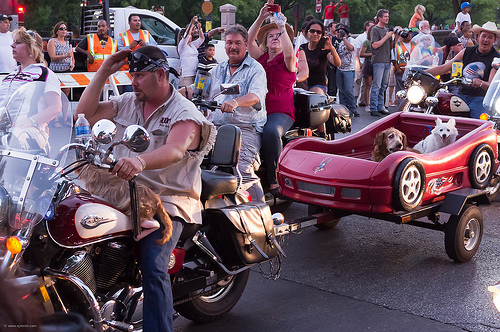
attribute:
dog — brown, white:
[373, 120, 423, 156]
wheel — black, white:
[395, 155, 428, 215]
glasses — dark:
[123, 48, 161, 71]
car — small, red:
[287, 105, 498, 179]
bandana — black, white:
[123, 64, 169, 77]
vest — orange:
[86, 22, 124, 72]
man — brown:
[94, 6, 122, 75]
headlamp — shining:
[4, 176, 51, 262]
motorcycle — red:
[3, 89, 264, 305]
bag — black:
[211, 186, 284, 270]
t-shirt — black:
[302, 42, 327, 90]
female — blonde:
[13, 23, 48, 67]